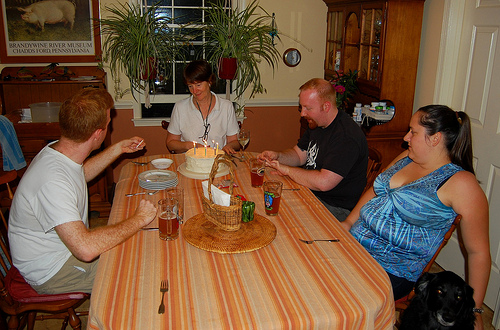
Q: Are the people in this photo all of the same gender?
A: No, they are both male and female.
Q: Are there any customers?
A: No, there are no customers.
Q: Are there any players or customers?
A: No, there are no customers or players.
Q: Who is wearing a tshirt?
A: The guy is wearing a tshirt.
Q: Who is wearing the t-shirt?
A: The guy is wearing a tshirt.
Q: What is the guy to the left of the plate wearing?
A: The guy is wearing a tee shirt.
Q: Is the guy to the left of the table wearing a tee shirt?
A: Yes, the guy is wearing a tee shirt.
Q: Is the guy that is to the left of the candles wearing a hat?
A: No, the guy is wearing a tee shirt.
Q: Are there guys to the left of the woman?
A: Yes, there is a guy to the left of the woman.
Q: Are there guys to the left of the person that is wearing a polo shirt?
A: Yes, there is a guy to the left of the woman.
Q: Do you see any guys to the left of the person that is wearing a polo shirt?
A: Yes, there is a guy to the left of the woman.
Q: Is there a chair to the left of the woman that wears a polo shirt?
A: No, there is a guy to the left of the woman.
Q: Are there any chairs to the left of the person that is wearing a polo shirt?
A: No, there is a guy to the left of the woman.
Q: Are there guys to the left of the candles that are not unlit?
A: Yes, there is a guy to the left of the candles.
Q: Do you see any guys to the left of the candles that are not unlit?
A: Yes, there is a guy to the left of the candles.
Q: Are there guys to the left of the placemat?
A: Yes, there is a guy to the left of the placemat.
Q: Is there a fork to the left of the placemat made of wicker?
A: No, there is a guy to the left of the place mat.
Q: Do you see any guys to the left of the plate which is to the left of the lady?
A: Yes, there is a guy to the left of the plate.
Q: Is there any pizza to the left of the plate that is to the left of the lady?
A: No, there is a guy to the left of the plate.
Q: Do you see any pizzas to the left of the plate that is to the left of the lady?
A: No, there is a guy to the left of the plate.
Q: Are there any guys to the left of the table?
A: Yes, there is a guy to the left of the table.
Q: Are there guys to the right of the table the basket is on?
A: No, the guy is to the left of the table.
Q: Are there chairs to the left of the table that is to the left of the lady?
A: No, there is a guy to the left of the table.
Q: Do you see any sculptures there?
A: No, there are no sculptures.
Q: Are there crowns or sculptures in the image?
A: No, there are no sculptures or crowns.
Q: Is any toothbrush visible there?
A: No, there are no toothbrushes.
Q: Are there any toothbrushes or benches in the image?
A: No, there are no toothbrushes or benches.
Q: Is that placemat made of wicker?
A: Yes, the placemat is made of wicker.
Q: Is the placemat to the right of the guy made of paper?
A: No, the place mat is made of wicker.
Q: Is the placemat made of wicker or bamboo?
A: The placemat is made of wicker.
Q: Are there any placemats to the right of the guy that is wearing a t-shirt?
A: Yes, there is a placemat to the right of the guy.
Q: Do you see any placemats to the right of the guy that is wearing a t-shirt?
A: Yes, there is a placemat to the right of the guy.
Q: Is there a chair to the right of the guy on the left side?
A: No, there is a placemat to the right of the guy.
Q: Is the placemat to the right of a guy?
A: Yes, the placemat is to the right of a guy.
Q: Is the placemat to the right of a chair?
A: No, the placemat is to the right of a guy.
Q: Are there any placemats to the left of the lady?
A: Yes, there is a placemat to the left of the lady.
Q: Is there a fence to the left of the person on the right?
A: No, there is a placemat to the left of the lady.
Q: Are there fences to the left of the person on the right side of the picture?
A: No, there is a placemat to the left of the lady.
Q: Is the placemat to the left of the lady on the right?
A: Yes, the placemat is to the left of the lady.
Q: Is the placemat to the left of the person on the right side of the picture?
A: Yes, the placemat is to the left of the lady.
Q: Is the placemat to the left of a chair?
A: No, the placemat is to the left of the lady.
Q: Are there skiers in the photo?
A: No, there are no skiers.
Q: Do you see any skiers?
A: No, there are no skiers.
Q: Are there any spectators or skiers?
A: No, there are no skiers or spectators.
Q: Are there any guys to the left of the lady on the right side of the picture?
A: Yes, there is a guy to the left of the lady.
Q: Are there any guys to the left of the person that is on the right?
A: Yes, there is a guy to the left of the lady.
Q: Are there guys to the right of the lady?
A: No, the guy is to the left of the lady.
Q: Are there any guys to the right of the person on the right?
A: No, the guy is to the left of the lady.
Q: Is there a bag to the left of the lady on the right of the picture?
A: No, there is a guy to the left of the lady.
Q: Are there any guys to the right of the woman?
A: Yes, there is a guy to the right of the woman.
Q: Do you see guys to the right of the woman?
A: Yes, there is a guy to the right of the woman.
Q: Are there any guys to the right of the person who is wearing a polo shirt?
A: Yes, there is a guy to the right of the woman.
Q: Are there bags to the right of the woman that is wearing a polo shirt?
A: No, there is a guy to the right of the woman.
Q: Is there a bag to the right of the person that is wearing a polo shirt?
A: No, there is a guy to the right of the woman.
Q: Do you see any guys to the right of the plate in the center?
A: Yes, there is a guy to the right of the plate.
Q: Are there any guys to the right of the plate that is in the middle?
A: Yes, there is a guy to the right of the plate.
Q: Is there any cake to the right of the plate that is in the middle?
A: No, there is a guy to the right of the plate.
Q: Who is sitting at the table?
A: The guy is sitting at the table.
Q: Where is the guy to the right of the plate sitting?
A: The guy is sitting at the table.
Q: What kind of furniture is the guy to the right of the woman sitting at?
A: The guy is sitting at the table.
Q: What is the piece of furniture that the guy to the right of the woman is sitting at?
A: The piece of furniture is a table.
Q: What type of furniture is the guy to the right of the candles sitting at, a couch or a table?
A: The guy is sitting at a table.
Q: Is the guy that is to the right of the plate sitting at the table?
A: Yes, the guy is sitting at the table.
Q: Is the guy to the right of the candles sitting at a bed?
A: No, the guy is sitting at the table.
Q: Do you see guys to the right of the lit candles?
A: Yes, there is a guy to the right of the candles.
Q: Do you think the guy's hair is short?
A: Yes, the hair is short.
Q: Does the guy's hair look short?
A: Yes, the hair is short.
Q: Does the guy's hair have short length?
A: Yes, the hair is short.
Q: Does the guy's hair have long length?
A: No, the hair is short.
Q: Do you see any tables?
A: Yes, there is a table.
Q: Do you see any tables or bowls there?
A: Yes, there is a table.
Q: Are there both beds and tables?
A: No, there is a table but no beds.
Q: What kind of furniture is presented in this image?
A: The furniture is a table.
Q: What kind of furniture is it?
A: The piece of furniture is a table.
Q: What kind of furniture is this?
A: This is a table.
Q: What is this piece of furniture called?
A: This is a table.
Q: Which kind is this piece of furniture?
A: This is a table.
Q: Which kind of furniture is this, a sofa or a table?
A: This is a table.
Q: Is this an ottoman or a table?
A: This is a table.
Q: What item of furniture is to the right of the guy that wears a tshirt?
A: The piece of furniture is a table.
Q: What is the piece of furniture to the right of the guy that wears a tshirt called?
A: The piece of furniture is a table.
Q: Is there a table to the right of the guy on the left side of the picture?
A: Yes, there is a table to the right of the guy.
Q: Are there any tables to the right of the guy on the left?
A: Yes, there is a table to the right of the guy.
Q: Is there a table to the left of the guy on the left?
A: No, the table is to the right of the guy.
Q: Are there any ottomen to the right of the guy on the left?
A: No, there is a table to the right of the guy.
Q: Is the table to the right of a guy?
A: Yes, the table is to the right of a guy.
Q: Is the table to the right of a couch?
A: No, the table is to the right of a guy.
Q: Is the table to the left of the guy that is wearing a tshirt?
A: No, the table is to the right of the guy.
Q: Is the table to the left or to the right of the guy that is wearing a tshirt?
A: The table is to the right of the guy.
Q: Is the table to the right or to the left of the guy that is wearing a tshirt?
A: The table is to the right of the guy.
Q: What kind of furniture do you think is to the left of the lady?
A: The piece of furniture is a table.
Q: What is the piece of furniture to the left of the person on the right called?
A: The piece of furniture is a table.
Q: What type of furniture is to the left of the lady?
A: The piece of furniture is a table.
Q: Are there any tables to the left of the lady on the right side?
A: Yes, there is a table to the left of the lady.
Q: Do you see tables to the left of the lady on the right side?
A: Yes, there is a table to the left of the lady.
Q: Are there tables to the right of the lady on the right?
A: No, the table is to the left of the lady.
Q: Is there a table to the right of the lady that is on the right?
A: No, the table is to the left of the lady.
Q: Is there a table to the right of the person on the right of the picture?
A: No, the table is to the left of the lady.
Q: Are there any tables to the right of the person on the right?
A: No, the table is to the left of the lady.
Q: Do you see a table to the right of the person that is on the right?
A: No, the table is to the left of the lady.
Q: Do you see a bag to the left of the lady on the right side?
A: No, there is a table to the left of the lady.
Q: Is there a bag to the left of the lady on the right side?
A: No, there is a table to the left of the lady.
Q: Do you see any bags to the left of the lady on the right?
A: No, there is a table to the left of the lady.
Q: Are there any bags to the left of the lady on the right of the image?
A: No, there is a table to the left of the lady.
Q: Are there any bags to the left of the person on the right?
A: No, there is a table to the left of the lady.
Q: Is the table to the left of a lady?
A: Yes, the table is to the left of a lady.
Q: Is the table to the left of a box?
A: No, the table is to the left of a lady.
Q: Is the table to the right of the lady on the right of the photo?
A: No, the table is to the left of the lady.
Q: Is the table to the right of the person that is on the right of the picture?
A: No, the table is to the left of the lady.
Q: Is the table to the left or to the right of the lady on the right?
A: The table is to the left of the lady.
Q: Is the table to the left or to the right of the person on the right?
A: The table is to the left of the lady.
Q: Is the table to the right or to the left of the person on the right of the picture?
A: The table is to the left of the lady.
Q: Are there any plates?
A: Yes, there is a plate.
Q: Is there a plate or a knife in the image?
A: Yes, there is a plate.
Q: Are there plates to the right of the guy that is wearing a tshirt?
A: Yes, there is a plate to the right of the guy.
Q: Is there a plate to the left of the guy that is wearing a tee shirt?
A: No, the plate is to the right of the guy.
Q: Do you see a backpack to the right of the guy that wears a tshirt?
A: No, there is a plate to the right of the guy.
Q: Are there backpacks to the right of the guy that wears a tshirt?
A: No, there is a plate to the right of the guy.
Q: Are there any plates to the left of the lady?
A: Yes, there is a plate to the left of the lady.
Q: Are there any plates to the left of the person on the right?
A: Yes, there is a plate to the left of the lady.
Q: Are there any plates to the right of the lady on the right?
A: No, the plate is to the left of the lady.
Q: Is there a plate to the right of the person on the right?
A: No, the plate is to the left of the lady.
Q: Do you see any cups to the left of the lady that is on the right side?
A: No, there is a plate to the left of the lady.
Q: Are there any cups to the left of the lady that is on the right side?
A: No, there is a plate to the left of the lady.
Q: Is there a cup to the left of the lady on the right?
A: No, there is a plate to the left of the lady.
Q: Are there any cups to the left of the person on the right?
A: No, there is a plate to the left of the lady.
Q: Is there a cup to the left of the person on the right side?
A: No, there is a plate to the left of the lady.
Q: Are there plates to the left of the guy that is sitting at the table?
A: Yes, there is a plate to the left of the guy.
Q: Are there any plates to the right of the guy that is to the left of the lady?
A: No, the plate is to the left of the guy.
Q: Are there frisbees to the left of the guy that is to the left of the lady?
A: No, there is a plate to the left of the guy.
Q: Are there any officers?
A: No, there are no officers.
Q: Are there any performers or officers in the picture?
A: No, there are no officers or performers.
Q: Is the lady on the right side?
A: Yes, the lady is on the right of the image.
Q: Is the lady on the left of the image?
A: No, the lady is on the right of the image.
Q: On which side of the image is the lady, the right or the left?
A: The lady is on the right of the image.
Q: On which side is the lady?
A: The lady is on the right of the image.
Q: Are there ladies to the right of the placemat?
A: Yes, there is a lady to the right of the placemat.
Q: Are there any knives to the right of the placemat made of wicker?
A: No, there is a lady to the right of the placemat.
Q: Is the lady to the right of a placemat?
A: Yes, the lady is to the right of a placemat.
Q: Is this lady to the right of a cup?
A: No, the lady is to the right of a placemat.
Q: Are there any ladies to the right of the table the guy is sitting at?
A: Yes, there is a lady to the right of the table.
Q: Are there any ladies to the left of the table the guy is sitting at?
A: No, the lady is to the right of the table.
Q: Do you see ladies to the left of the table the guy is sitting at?
A: No, the lady is to the right of the table.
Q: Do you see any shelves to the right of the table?
A: No, there is a lady to the right of the table.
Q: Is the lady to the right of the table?
A: Yes, the lady is to the right of the table.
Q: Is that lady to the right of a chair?
A: No, the lady is to the right of the table.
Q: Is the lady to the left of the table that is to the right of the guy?
A: No, the lady is to the right of the table.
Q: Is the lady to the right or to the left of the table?
A: The lady is to the right of the table.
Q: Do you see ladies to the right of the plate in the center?
A: Yes, there is a lady to the right of the plate.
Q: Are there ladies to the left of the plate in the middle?
A: No, the lady is to the right of the plate.